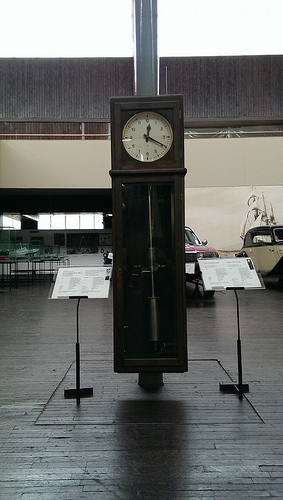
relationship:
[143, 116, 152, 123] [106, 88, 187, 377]
number on clock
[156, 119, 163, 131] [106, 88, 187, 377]
number on clock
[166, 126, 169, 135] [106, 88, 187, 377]
number on clock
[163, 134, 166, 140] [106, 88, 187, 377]
number on clock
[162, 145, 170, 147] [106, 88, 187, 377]
number on clock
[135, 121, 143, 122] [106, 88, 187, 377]
number on clock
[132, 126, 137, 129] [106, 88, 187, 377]
number on clock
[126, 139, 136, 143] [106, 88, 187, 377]
number on clock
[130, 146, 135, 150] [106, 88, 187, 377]
number on clock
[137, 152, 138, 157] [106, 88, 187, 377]
number on clock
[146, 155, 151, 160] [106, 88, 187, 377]
number on clock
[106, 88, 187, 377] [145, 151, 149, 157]
clock reads number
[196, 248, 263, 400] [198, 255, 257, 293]
stands holds paper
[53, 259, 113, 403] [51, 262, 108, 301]
stand holds paper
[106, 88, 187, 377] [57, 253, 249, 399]
clock between stands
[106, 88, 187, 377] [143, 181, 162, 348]
clock has chime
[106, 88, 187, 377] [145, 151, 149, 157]
clock has number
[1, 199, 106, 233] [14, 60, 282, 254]
windows in wall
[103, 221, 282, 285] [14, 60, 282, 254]
cars in background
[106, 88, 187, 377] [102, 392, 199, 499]
clock cast shadow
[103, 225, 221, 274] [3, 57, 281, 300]
car in background.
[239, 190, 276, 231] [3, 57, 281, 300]
ship in background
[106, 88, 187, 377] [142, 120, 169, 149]
clock reads 12:20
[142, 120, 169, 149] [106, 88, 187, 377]
12:20 on clock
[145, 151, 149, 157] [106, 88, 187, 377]
number on clock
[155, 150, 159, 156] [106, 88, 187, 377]
number on clock